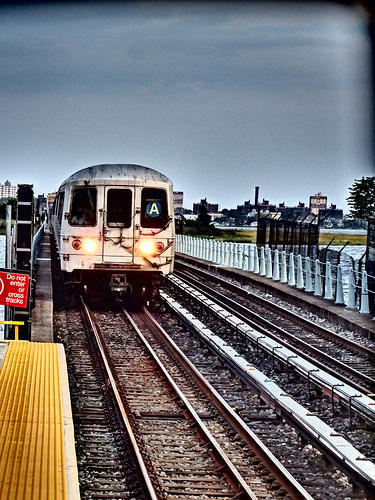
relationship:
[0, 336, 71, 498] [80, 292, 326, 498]
grate next to tracks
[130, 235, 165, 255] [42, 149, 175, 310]
light on front of train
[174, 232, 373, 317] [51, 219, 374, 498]
fence along train tracks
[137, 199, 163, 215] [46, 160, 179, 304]
blue sign on train